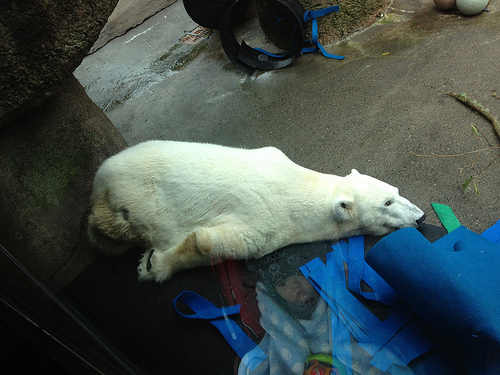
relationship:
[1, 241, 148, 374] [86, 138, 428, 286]
wood next to bear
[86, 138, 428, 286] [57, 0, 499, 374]
bear laying on ground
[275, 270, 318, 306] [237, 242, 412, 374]
face of child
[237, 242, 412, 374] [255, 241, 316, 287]
child in bandana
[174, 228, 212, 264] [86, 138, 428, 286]
spot on bear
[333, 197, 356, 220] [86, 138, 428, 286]
ear on bear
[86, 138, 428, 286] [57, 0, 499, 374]
bear on ground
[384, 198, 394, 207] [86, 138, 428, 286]
eye of bear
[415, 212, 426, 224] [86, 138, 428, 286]
nose of bear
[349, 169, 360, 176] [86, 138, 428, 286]
ear of bear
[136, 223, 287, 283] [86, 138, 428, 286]
leg of bear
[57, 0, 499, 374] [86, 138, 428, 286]
ground beneath bear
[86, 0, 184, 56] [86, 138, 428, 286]
wall behind bear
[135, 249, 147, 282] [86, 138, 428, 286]
claws of bear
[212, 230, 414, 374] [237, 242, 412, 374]
reflection of child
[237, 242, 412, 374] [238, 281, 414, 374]
child in blanket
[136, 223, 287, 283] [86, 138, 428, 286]
arm of bear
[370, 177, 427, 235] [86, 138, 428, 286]
face of bear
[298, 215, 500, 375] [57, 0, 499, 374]
fabric on ground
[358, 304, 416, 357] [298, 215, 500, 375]
piece of fabric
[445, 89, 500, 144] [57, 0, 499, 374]
stick on ground